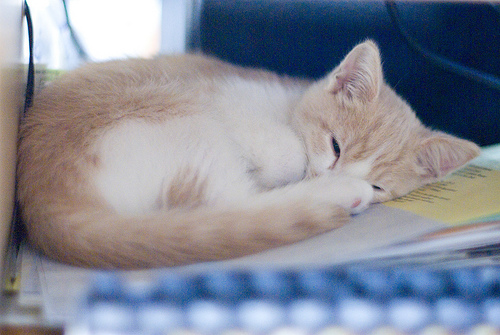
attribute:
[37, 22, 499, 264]
cat — white , brown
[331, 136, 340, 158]
eye — cat's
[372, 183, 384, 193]
eye — cat's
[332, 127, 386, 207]
eyes — half closed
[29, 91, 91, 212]
fur — white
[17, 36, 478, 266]
cat — tail, adorable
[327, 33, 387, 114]
ear — cats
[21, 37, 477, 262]
fur — orange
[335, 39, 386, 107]
ear — inner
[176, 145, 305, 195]
fur — white